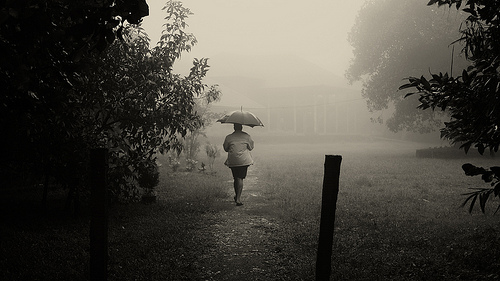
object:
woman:
[214, 105, 265, 205]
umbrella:
[215, 105, 267, 128]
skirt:
[230, 164, 250, 179]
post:
[90, 149, 109, 280]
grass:
[257, 141, 500, 281]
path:
[207, 146, 273, 279]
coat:
[222, 131, 254, 166]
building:
[207, 80, 374, 136]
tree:
[345, 0, 475, 146]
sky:
[146, 0, 369, 95]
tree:
[26, 0, 222, 201]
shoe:
[235, 202, 243, 206]